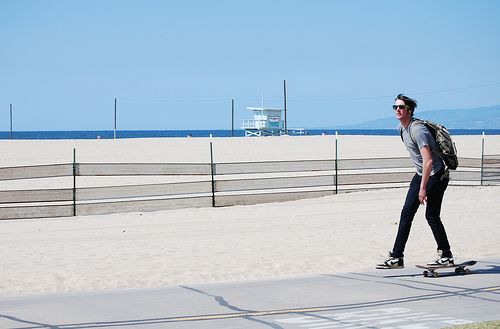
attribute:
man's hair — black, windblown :
[398, 92, 415, 109]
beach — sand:
[3, 130, 499, 298]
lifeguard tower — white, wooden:
[240, 103, 286, 142]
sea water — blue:
[1, 128, 495, 131]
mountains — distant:
[346, 105, 498, 129]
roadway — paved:
[1, 260, 496, 326]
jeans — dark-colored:
[389, 167, 450, 257]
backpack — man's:
[416, 118, 461, 174]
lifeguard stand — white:
[239, 100, 288, 135]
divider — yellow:
[83, 283, 497, 324]